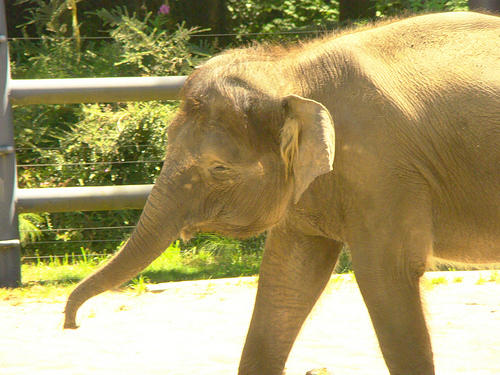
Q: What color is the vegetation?
A: Green.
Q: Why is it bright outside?
A: It's daytime.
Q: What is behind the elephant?
A: A fence.